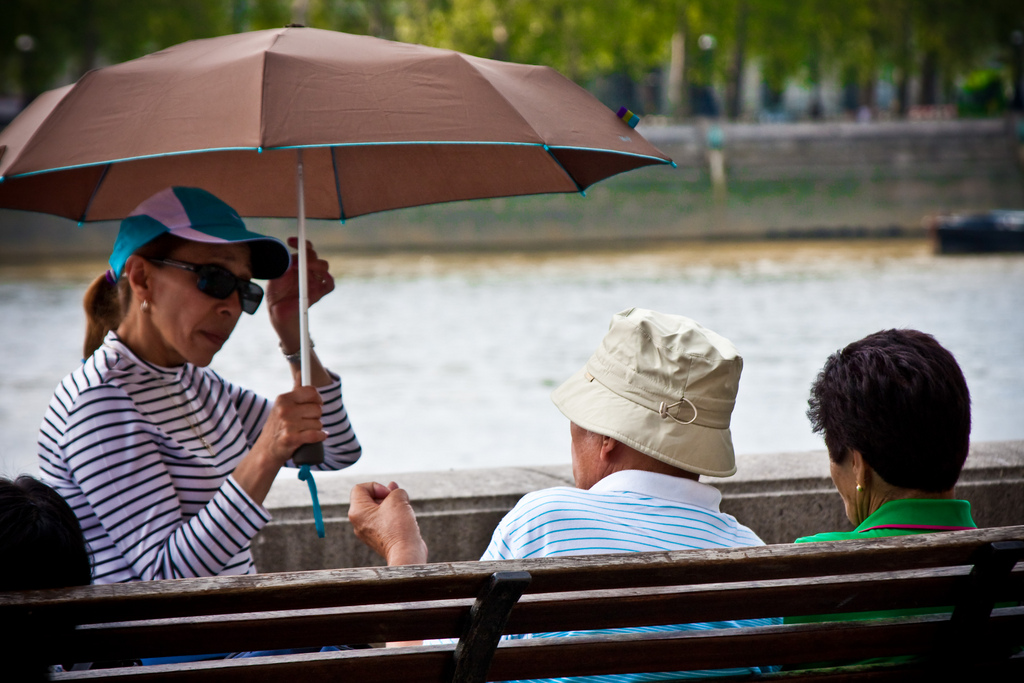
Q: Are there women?
A: Yes, there is a woman.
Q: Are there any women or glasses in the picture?
A: Yes, there is a woman.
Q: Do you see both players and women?
A: No, there is a woman but no players.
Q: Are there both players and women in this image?
A: No, there is a woman but no players.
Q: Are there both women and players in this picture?
A: No, there is a woman but no players.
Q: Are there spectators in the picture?
A: No, there are no spectators.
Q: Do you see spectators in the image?
A: No, there are no spectators.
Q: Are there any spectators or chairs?
A: No, there are no spectators or chairs.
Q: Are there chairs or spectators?
A: No, there are no spectators or chairs.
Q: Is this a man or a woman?
A: This is a woman.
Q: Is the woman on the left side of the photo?
A: Yes, the woman is on the left of the image.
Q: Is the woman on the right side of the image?
A: No, the woman is on the left of the image.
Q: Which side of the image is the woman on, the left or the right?
A: The woman is on the left of the image.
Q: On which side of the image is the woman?
A: The woman is on the left of the image.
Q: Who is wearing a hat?
A: The woman is wearing a hat.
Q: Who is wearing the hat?
A: The woman is wearing a hat.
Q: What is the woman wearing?
A: The woman is wearing a hat.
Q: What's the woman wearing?
A: The woman is wearing a hat.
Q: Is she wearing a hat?
A: Yes, the woman is wearing a hat.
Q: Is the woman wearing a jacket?
A: No, the woman is wearing a hat.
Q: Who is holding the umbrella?
A: The woman is holding the umbrella.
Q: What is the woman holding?
A: The woman is holding the umbrella.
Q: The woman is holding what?
A: The woman is holding the umbrella.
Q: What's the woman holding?
A: The woman is holding the umbrella.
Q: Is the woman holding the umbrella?
A: Yes, the woman is holding the umbrella.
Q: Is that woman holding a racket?
A: No, the woman is holding the umbrella.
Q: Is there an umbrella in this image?
A: Yes, there is an umbrella.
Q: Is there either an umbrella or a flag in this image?
A: Yes, there is an umbrella.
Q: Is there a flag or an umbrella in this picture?
A: Yes, there is an umbrella.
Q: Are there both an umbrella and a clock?
A: No, there is an umbrella but no clocks.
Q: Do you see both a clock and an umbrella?
A: No, there is an umbrella but no clocks.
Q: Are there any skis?
A: No, there are no skis.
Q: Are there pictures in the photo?
A: No, there are no pictures.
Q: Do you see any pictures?
A: No, there are no pictures.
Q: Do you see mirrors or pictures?
A: No, there are no pictures or mirrors.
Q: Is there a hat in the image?
A: Yes, there is a hat.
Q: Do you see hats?
A: Yes, there is a hat.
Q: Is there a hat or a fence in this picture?
A: Yes, there is a hat.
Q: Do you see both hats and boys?
A: No, there is a hat but no boys.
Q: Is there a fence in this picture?
A: No, there are no fences.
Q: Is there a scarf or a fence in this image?
A: No, there are no fences or scarves.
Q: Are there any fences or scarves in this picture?
A: No, there are no fences or scarves.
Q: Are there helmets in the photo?
A: No, there are no helmets.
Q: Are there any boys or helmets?
A: No, there are no helmets or boys.